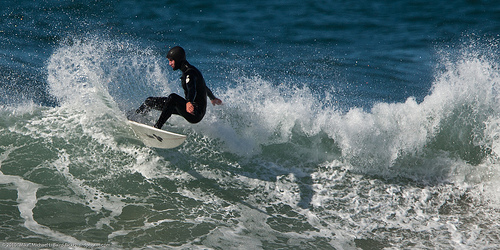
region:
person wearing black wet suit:
[135, 37, 235, 145]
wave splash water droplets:
[233, 50, 345, 100]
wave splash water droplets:
[11, 22, 76, 97]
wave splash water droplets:
[440, 32, 498, 52]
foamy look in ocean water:
[345, 180, 445, 232]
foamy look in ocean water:
[13, 166, 73, 233]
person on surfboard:
[116, 39, 232, 168]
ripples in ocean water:
[254, 17, 382, 78]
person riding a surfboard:
[108, 30, 233, 166]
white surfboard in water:
[121, 109, 196, 156]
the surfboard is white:
[110, 115, 200, 158]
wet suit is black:
[123, 22, 218, 129]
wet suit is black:
[96, 49, 246, 169]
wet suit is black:
[87, 32, 287, 226]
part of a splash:
[260, 73, 330, 174]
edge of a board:
[164, 119, 195, 151]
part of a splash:
[338, 113, 381, 183]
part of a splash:
[335, 83, 383, 165]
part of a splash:
[376, 91, 410, 131]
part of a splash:
[223, 38, 280, 151]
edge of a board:
[165, 117, 195, 159]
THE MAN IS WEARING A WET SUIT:
[120, 35, 227, 138]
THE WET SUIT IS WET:
[121, 32, 224, 130]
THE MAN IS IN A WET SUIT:
[121, 36, 234, 137]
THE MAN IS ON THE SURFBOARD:
[107, 35, 227, 160]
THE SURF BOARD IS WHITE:
[110, 106, 186, 157]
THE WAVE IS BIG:
[5, 41, 482, 247]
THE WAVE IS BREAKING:
[7, 40, 495, 248]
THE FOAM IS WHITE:
[2, 146, 317, 247]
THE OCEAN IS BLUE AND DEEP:
[1, 2, 496, 230]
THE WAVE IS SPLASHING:
[30, 35, 498, 179]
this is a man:
[140, 37, 220, 129]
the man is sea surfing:
[135, 54, 212, 122]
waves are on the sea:
[268, 93, 422, 170]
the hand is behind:
[178, 88, 201, 115]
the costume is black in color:
[184, 70, 199, 90]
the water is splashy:
[264, 89, 353, 126]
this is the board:
[152, 131, 191, 155]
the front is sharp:
[170, 128, 187, 151]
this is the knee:
[167, 91, 181, 102]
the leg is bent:
[151, 91, 181, 121]